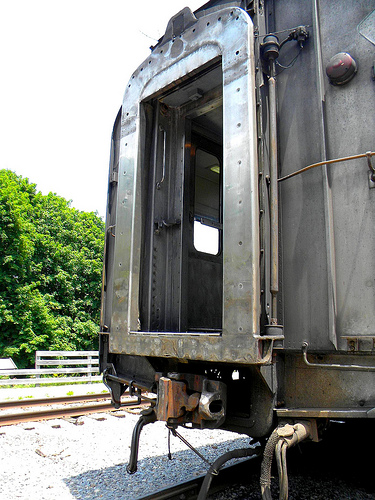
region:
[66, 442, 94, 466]
THE PEBBLES ARE WHITE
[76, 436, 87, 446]
THE PEBBLES ARE WHITE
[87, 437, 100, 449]
THE PEBBLES ARE WHITE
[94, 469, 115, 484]
THE PEBBLES ARE WHITE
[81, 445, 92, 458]
THE PEBBLES ARE WHITE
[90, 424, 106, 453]
THE PEBBLES ARE WHITE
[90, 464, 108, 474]
THE PEBBLES ARE WHITE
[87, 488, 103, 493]
THE PEBBLES ARE WHITE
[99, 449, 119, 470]
THE PEBBLES ARE WHITE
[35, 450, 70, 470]
THE PEBBLES ARE WHITE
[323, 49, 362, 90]
a red light is on the train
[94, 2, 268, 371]
the back door of the train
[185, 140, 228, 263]
the window has a shade in it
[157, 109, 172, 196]
a grab bar at the back door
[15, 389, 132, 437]
train tracks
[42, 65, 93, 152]
it appears to be a cloudy day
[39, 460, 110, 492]
white gravel is in between the tracks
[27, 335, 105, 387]
the fence is white rails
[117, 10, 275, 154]
holes are around the edges of the door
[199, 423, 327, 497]
various hoses on the back of the train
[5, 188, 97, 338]
Trees are in the background.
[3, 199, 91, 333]
The trees are green.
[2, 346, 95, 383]
A fence is in the background.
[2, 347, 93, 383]
The fence is made of wood.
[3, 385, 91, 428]
A pair of train tracks.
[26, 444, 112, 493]
Gravel is between the tracks.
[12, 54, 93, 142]
The sky is bright.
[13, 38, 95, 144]
The sky is white.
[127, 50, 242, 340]
The train door is open.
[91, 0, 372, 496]
A train car.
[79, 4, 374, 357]
a silver train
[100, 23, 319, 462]
a train with door open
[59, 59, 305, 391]
a silver train with door open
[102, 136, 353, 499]
a silver train on tracks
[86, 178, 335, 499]
a train on tracks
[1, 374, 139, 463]
train tracks on rocks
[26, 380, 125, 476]
rocks surround train tracks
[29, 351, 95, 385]
a white wooden fence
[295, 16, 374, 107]
a train with red light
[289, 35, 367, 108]
a train with brake light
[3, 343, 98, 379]
A fence.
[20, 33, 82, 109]
The sky is white.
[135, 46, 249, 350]
A door on the train.